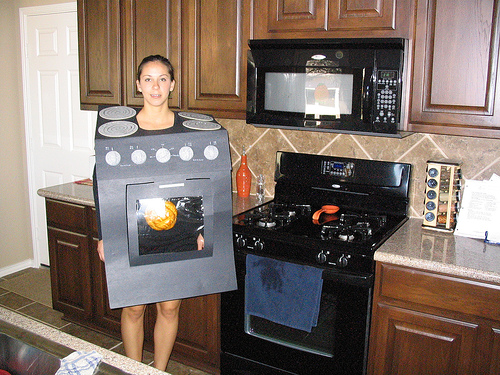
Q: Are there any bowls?
A: No, there are no bowls.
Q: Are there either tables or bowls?
A: No, there are no bowls or tables.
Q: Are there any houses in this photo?
A: No, there are no houses.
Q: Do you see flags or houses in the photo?
A: No, there are no houses or flags.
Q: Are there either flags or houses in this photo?
A: No, there are no houses or flags.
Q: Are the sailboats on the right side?
A: Yes, the sailboats are on the right of the image.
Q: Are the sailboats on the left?
A: No, the sailboats are on the right of the image.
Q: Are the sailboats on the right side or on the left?
A: The sailboats are on the right of the image.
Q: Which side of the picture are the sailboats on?
A: The sailboats are on the right of the image.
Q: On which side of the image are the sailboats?
A: The sailboats are on the right of the image.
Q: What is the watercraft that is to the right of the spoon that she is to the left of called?
A: The watercraft is sailboats.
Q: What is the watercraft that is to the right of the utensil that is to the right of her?
A: The watercraft is sailboats.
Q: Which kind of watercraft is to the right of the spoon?
A: The watercraft is sailboats.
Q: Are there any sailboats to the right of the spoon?
A: Yes, there are sailboats to the right of the spoon.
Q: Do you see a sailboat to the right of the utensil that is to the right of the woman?
A: Yes, there are sailboats to the right of the spoon.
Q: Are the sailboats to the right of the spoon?
A: Yes, the sailboats are to the right of the spoon.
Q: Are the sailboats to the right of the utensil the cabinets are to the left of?
A: Yes, the sailboats are to the right of the spoon.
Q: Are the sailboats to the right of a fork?
A: No, the sailboats are to the right of the spoon.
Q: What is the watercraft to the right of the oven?
A: The watercraft is sailboats.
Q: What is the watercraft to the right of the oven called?
A: The watercraft is sailboats.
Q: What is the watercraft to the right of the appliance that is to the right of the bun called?
A: The watercraft is sailboats.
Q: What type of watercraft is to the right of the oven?
A: The watercraft is sailboats.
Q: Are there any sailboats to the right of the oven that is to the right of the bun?
A: Yes, there are sailboats to the right of the oven.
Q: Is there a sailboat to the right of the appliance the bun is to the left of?
A: Yes, there are sailboats to the right of the oven.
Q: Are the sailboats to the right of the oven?
A: Yes, the sailboats are to the right of the oven.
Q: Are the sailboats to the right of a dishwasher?
A: No, the sailboats are to the right of the oven.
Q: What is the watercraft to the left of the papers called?
A: The watercraft is sailboats.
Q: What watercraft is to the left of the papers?
A: The watercraft is sailboats.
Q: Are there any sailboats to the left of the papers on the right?
A: Yes, there are sailboats to the left of the papers.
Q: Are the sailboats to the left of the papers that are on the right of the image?
A: Yes, the sailboats are to the left of the papers.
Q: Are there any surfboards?
A: No, there are no surfboards.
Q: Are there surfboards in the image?
A: No, there are no surfboards.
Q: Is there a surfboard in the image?
A: No, there are no surfboards.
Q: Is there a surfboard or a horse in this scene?
A: No, there are no surfboards or horses.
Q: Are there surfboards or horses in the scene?
A: No, there are no surfboards or horses.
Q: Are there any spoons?
A: Yes, there is a spoon.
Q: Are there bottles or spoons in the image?
A: Yes, there is a spoon.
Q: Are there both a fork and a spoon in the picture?
A: No, there is a spoon but no forks.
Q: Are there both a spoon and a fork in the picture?
A: No, there is a spoon but no forks.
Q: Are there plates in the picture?
A: No, there are no plates.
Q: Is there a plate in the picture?
A: No, there are no plates.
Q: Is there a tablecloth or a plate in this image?
A: No, there are no plates or tablecloths.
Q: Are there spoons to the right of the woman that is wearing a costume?
A: Yes, there is a spoon to the right of the woman.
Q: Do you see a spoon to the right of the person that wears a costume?
A: Yes, there is a spoon to the right of the woman.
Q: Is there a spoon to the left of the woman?
A: No, the spoon is to the right of the woman.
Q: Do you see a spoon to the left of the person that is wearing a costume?
A: No, the spoon is to the right of the woman.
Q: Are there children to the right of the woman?
A: No, there is a spoon to the right of the woman.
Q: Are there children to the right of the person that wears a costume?
A: No, there is a spoon to the right of the woman.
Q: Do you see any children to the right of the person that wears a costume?
A: No, there is a spoon to the right of the woman.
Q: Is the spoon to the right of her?
A: Yes, the spoon is to the right of a woman.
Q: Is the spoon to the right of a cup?
A: No, the spoon is to the right of a woman.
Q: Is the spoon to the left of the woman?
A: No, the spoon is to the right of the woman.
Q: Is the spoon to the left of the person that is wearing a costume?
A: No, the spoon is to the right of the woman.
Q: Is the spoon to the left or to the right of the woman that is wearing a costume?
A: The spoon is to the right of the woman.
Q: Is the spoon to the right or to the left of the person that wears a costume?
A: The spoon is to the right of the woman.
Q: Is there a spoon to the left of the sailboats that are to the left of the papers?
A: Yes, there is a spoon to the left of the sailboats.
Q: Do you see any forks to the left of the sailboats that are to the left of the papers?
A: No, there is a spoon to the left of the sailboats.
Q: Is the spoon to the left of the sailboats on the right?
A: Yes, the spoon is to the left of the sailboats.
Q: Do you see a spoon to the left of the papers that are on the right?
A: Yes, there is a spoon to the left of the papers.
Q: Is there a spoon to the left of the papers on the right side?
A: Yes, there is a spoon to the left of the papers.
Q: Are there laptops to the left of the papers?
A: No, there is a spoon to the left of the papers.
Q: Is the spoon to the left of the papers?
A: Yes, the spoon is to the left of the papers.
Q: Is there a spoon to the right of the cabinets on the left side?
A: Yes, there is a spoon to the right of the cabinets.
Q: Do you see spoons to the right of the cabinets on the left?
A: Yes, there is a spoon to the right of the cabinets.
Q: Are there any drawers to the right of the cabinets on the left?
A: No, there is a spoon to the right of the cabinets.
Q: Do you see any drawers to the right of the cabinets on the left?
A: No, there is a spoon to the right of the cabinets.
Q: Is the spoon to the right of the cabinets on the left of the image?
A: Yes, the spoon is to the right of the cabinets.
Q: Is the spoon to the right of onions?
A: No, the spoon is to the right of the cabinets.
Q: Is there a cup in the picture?
A: No, there are no cups.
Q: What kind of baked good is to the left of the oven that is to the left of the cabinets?
A: The food is a bun.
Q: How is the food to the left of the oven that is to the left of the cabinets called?
A: The food is a bun.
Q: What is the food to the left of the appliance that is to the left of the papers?
A: The food is a bun.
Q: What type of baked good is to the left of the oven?
A: The food is a bun.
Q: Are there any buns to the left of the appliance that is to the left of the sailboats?
A: Yes, there is a bun to the left of the oven.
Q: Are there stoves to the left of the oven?
A: No, there is a bun to the left of the oven.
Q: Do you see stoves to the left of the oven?
A: No, there is a bun to the left of the oven.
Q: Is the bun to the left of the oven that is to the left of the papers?
A: Yes, the bun is to the left of the oven.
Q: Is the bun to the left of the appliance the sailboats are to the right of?
A: Yes, the bun is to the left of the oven.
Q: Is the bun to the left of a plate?
A: No, the bun is to the left of the oven.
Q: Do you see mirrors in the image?
A: No, there are no mirrors.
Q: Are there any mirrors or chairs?
A: No, there are no mirrors or chairs.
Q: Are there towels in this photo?
A: Yes, there is a towel.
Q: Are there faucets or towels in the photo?
A: Yes, there is a towel.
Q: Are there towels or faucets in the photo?
A: Yes, there is a towel.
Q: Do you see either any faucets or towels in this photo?
A: Yes, there is a towel.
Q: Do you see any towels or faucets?
A: Yes, there is a towel.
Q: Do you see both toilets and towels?
A: No, there is a towel but no toilets.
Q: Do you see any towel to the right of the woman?
A: Yes, there is a towel to the right of the woman.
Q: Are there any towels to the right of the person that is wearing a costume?
A: Yes, there is a towel to the right of the woman.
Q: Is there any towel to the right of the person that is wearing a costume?
A: Yes, there is a towel to the right of the woman.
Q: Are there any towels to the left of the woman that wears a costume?
A: No, the towel is to the right of the woman.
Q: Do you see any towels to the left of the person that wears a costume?
A: No, the towel is to the right of the woman.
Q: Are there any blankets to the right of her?
A: No, there is a towel to the right of the woman.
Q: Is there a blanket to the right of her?
A: No, there is a towel to the right of the woman.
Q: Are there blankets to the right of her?
A: No, there is a towel to the right of the woman.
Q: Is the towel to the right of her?
A: Yes, the towel is to the right of the woman.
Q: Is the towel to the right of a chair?
A: No, the towel is to the right of the woman.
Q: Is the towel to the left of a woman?
A: No, the towel is to the right of a woman.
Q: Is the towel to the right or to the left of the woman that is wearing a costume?
A: The towel is to the right of the woman.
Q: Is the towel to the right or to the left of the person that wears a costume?
A: The towel is to the right of the woman.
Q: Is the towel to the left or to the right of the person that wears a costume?
A: The towel is to the right of the woman.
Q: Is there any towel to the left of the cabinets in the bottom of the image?
A: Yes, there is a towel to the left of the cabinets.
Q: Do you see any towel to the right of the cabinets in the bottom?
A: No, the towel is to the left of the cabinets.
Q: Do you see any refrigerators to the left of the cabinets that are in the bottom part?
A: No, there is a towel to the left of the cabinets.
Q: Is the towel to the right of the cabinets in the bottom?
A: No, the towel is to the left of the cabinets.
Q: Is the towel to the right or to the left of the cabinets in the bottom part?
A: The towel is to the left of the cabinets.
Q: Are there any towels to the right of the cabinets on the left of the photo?
A: Yes, there is a towel to the right of the cabinets.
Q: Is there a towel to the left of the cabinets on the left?
A: No, the towel is to the right of the cabinets.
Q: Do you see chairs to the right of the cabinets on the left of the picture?
A: No, there is a towel to the right of the cabinets.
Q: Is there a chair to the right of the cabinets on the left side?
A: No, there is a towel to the right of the cabinets.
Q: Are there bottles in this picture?
A: Yes, there is a bottle.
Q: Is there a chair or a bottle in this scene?
A: Yes, there is a bottle.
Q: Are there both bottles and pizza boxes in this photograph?
A: No, there is a bottle but no pizza boxes.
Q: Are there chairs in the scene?
A: No, there are no chairs.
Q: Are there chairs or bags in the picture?
A: No, there are no chairs or bags.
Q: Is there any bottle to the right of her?
A: Yes, there is a bottle to the right of the woman.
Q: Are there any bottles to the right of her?
A: Yes, there is a bottle to the right of the woman.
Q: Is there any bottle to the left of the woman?
A: No, the bottle is to the right of the woman.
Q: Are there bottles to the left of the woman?
A: No, the bottle is to the right of the woman.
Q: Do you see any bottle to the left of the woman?
A: No, the bottle is to the right of the woman.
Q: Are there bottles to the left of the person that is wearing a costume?
A: No, the bottle is to the right of the woman.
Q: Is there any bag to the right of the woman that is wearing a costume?
A: No, there is a bottle to the right of the woman.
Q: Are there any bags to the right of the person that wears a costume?
A: No, there is a bottle to the right of the woman.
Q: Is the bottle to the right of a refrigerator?
A: No, the bottle is to the right of a woman.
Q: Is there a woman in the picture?
A: Yes, there is a woman.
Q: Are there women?
A: Yes, there is a woman.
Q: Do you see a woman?
A: Yes, there is a woman.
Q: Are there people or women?
A: Yes, there is a woman.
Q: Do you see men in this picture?
A: No, there are no men.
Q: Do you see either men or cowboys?
A: No, there are no men or cowboys.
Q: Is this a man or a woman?
A: This is a woman.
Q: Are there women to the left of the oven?
A: Yes, there is a woman to the left of the oven.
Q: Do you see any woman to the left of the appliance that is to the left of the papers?
A: Yes, there is a woman to the left of the oven.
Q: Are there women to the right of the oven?
A: No, the woman is to the left of the oven.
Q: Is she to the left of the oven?
A: Yes, the woman is to the left of the oven.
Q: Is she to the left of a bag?
A: No, the woman is to the left of the oven.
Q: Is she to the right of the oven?
A: No, the woman is to the left of the oven.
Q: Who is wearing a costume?
A: The woman is wearing a costume.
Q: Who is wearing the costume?
A: The woman is wearing a costume.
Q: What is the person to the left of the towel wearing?
A: The woman is wearing a costume.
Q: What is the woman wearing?
A: The woman is wearing a costume.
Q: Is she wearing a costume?
A: Yes, the woman is wearing a costume.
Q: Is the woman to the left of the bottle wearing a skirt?
A: No, the woman is wearing a costume.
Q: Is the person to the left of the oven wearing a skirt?
A: No, the woman is wearing a costume.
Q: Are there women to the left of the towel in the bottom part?
A: Yes, there is a woman to the left of the towel.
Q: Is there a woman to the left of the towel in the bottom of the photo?
A: Yes, there is a woman to the left of the towel.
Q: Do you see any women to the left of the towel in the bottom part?
A: Yes, there is a woman to the left of the towel.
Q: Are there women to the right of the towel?
A: No, the woman is to the left of the towel.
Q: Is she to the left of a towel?
A: Yes, the woman is to the left of a towel.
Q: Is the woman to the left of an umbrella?
A: No, the woman is to the left of a towel.